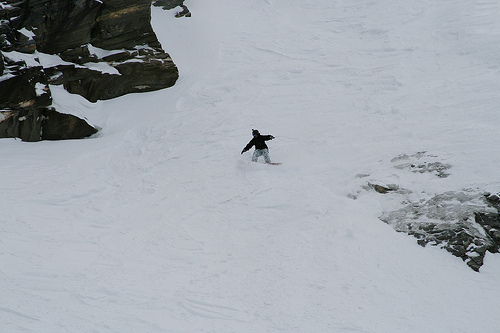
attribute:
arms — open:
[237, 132, 276, 154]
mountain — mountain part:
[0, 2, 497, 330]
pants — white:
[248, 147, 274, 163]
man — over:
[238, 126, 279, 168]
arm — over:
[262, 133, 277, 142]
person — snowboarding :
[243, 127, 274, 165]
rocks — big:
[1, 1, 193, 143]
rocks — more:
[395, 194, 497, 254]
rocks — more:
[0, 0, 177, 142]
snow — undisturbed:
[0, 3, 498, 330]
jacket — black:
[240, 135, 270, 150]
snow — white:
[66, 263, 268, 332]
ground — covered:
[187, 204, 441, 318]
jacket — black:
[236, 125, 291, 154]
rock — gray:
[356, 161, 490, 291]